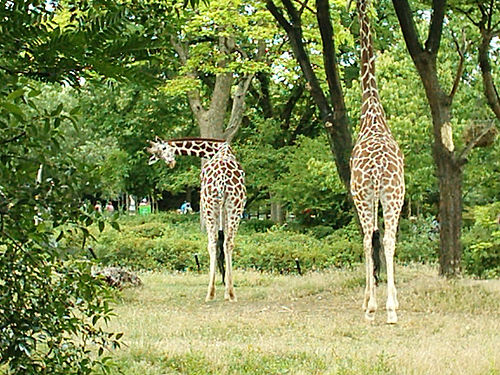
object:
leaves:
[107, 220, 123, 234]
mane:
[163, 135, 228, 144]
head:
[138, 134, 185, 169]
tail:
[214, 181, 230, 286]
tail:
[368, 164, 384, 287]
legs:
[223, 195, 242, 293]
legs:
[358, 159, 376, 303]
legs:
[380, 169, 401, 301]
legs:
[204, 184, 217, 293]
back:
[351, 176, 400, 222]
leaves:
[113, 330, 128, 339]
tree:
[379, 0, 494, 279]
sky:
[265, 53, 295, 113]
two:
[142, 0, 406, 327]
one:
[344, 1, 406, 328]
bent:
[174, 135, 210, 160]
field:
[0, 261, 499, 375]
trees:
[389, 1, 496, 280]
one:
[146, 135, 246, 303]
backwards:
[138, 135, 180, 170]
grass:
[0, 264, 499, 373]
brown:
[215, 290, 358, 318]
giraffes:
[328, 0, 405, 325]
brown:
[232, 175, 235, 184]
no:
[151, 176, 442, 305]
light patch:
[438, 122, 456, 151]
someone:
[168, 189, 198, 223]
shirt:
[182, 205, 186, 209]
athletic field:
[35, 180, 199, 216]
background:
[0, 0, 499, 375]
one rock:
[96, 267, 142, 288]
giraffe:
[141, 130, 250, 304]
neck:
[169, 136, 217, 157]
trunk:
[394, 2, 464, 278]